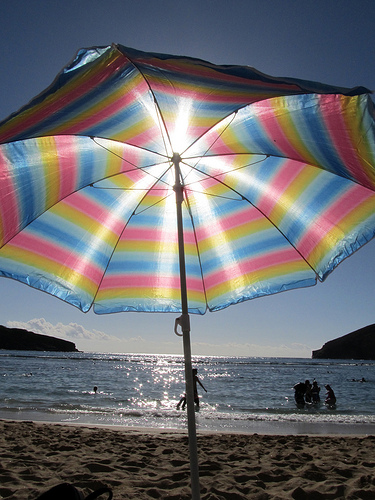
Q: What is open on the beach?
A: An umbrella.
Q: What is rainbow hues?
A: An umbrella.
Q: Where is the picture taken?
A: A beach.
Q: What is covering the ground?
A: Sand.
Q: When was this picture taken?
A: Early evening.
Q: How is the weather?
A: Clear.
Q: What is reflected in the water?
A: Sun.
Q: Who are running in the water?
A: Children.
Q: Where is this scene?
A: At the beach.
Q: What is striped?
A: The beach umbrella.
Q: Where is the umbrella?
A: In the sand.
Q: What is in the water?
A: A group of people.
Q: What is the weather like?
A: Sunny and blue.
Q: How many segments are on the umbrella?
A: Eight.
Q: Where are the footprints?
A: In the sand.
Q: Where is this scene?
A: At the beach.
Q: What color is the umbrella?
A: Blue, pink, and yellow.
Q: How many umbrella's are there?
A: One.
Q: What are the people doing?
A: Swimming.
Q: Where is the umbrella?
A: On the beach.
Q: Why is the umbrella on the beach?
A: Providing shade.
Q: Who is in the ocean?
A: People.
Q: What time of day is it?
A: Day time.